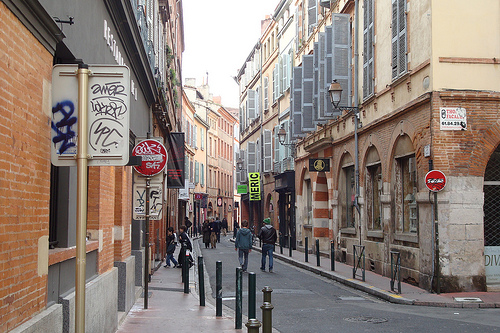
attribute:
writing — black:
[250, 172, 258, 203]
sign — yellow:
[246, 172, 261, 203]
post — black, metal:
[182, 246, 191, 296]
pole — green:
[196, 252, 206, 307]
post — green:
[209, 257, 229, 319]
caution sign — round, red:
[424, 167, 446, 193]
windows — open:
[269, 32, 372, 114]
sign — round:
[402, 169, 468, 197]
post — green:
[281, 222, 311, 264]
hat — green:
[252, 212, 276, 224]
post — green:
[225, 264, 254, 331]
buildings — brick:
[7, 1, 499, 332]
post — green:
[303, 234, 312, 266]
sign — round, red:
[132, 137, 169, 176]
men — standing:
[229, 220, 276, 272]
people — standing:
[166, 225, 191, 260]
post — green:
[244, 273, 256, 318]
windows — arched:
[40, 66, 137, 275]